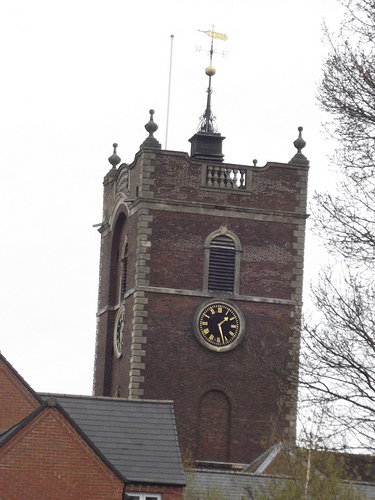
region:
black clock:
[195, 293, 245, 356]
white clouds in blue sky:
[27, 60, 52, 97]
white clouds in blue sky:
[17, 174, 52, 215]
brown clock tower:
[101, 134, 293, 402]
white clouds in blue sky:
[50, 275, 77, 306]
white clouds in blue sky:
[30, 102, 68, 150]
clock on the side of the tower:
[190, 295, 255, 355]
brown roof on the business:
[82, 399, 182, 476]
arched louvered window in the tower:
[192, 221, 251, 293]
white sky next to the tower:
[24, 202, 78, 281]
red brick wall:
[15, 443, 76, 494]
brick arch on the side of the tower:
[191, 377, 238, 465]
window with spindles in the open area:
[202, 170, 255, 195]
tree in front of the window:
[300, 277, 361, 454]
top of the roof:
[71, 390, 129, 403]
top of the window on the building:
[126, 490, 164, 499]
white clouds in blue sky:
[24, 63, 66, 83]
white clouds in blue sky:
[37, 250, 77, 300]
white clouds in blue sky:
[22, 54, 80, 126]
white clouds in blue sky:
[221, 38, 291, 95]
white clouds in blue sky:
[233, 67, 264, 139]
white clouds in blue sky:
[110, 20, 144, 68]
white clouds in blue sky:
[42, 123, 70, 166]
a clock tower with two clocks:
[94, 23, 309, 469]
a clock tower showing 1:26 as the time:
[192, 298, 246, 353]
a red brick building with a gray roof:
[0, 351, 187, 495]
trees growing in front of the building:
[183, 0, 371, 496]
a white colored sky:
[6, 0, 371, 455]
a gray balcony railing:
[201, 159, 251, 191]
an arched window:
[200, 226, 238, 295]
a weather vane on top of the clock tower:
[91, 22, 308, 472]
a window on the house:
[120, 493, 162, 497]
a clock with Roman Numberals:
[195, 297, 244, 350]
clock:
[176, 291, 246, 366]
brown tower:
[117, 40, 326, 427]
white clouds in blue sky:
[30, 88, 65, 139]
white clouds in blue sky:
[26, 208, 60, 277]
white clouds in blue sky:
[48, 275, 78, 324]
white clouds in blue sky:
[43, 64, 84, 105]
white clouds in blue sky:
[88, 21, 122, 62]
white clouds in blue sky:
[120, 19, 176, 93]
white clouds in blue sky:
[248, 25, 280, 83]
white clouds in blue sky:
[32, 226, 54, 241]